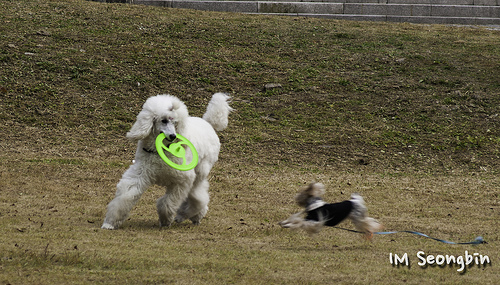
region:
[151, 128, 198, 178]
neon green circle frisbee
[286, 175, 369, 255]
blurry dog running in the park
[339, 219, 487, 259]
blue leash on dog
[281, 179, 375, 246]
brown white and black dog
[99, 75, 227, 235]
hairy white dog in park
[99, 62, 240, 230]
dog holding green frisbee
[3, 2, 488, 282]
green and brown grass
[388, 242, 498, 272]
"im seongbin" water mark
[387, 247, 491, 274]
"im seongbin" in white letters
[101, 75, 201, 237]
this is a dog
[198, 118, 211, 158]
the dog is white in color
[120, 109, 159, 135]
this is the ear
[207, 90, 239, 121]
this is the tail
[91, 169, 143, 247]
this is the leg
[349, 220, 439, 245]
this is a rope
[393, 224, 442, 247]
the rope is blue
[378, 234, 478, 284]
this is a writing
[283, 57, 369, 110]
this is a grass area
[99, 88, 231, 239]
this is a dog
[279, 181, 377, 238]
this is a dog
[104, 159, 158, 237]
this is a dog's leg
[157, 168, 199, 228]
this is a dog's leg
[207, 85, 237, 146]
this is a dog's tail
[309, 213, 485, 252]
this is a rope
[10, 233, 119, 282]
this is dry vegetation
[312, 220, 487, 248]
a blue leash attached to a small dog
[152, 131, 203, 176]
lime green frisbee in the poodle's mouth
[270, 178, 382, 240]
a small dog running on the ground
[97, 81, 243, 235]
a poodle playing frisbee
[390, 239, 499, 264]
text on the bottom right corner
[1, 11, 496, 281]
dirt and patchy grass on the ground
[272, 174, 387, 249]
a tricolor small terrier playing frisbee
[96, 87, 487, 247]
two dogs playing together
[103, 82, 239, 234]
the poodle has a frisbee in its mouth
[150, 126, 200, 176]
Dog carrying a frisbee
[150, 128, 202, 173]
Dog is carrying a frisbee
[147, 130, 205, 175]
Dog carrying a green frisbee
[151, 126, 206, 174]
Dog is carrying a green frisbee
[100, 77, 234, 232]
Dog on the grass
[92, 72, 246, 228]
Dog is on the grass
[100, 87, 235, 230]
White dog on the grass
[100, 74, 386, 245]
Dogs playing on the grass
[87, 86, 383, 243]
Dogs are playing on the grass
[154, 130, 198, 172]
the toy is green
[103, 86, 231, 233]
white puddle in the ground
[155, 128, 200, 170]
green frisbee on the mouth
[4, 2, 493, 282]
short green grass on the ground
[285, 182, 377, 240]
small black and white dog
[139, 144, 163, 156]
black necklace of white dog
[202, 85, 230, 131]
white furry tail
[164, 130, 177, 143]
small dark nose of white dog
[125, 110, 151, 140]
small furry right ear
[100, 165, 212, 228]
four legs of white dog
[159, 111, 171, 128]
small round black right eye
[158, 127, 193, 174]
frisbee is green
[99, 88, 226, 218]
white poodle is holding a frisbee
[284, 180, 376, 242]
a little dog chasing the poodle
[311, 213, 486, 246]
blue leash on the little dog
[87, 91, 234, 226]
poodle is wearing a black collar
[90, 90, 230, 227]
poodle is running